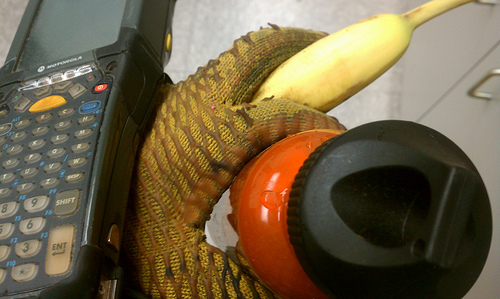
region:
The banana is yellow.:
[255, 22, 460, 114]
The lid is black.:
[290, 120, 498, 295]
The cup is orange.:
[204, 130, 364, 296]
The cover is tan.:
[120, 32, 317, 296]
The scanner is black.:
[3, 5, 143, 297]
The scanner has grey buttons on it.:
[0, 27, 129, 292]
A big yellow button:
[18, 80, 80, 123]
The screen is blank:
[8, 2, 493, 297]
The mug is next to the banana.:
[208, 112, 498, 294]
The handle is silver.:
[458, 57, 497, 101]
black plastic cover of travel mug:
[286, 108, 498, 297]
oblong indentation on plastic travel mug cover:
[314, 151, 439, 259]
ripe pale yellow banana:
[264, 0, 477, 112]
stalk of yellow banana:
[390, 2, 472, 29]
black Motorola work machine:
[6, 1, 161, 296]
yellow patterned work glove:
[164, 23, 226, 292]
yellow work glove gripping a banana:
[176, 6, 453, 131]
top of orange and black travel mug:
[233, 118, 495, 297]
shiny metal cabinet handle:
[460, 56, 499, 108]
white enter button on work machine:
[41, 223, 79, 278]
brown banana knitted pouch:
[215, 19, 378, 135]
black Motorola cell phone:
[10, 11, 135, 284]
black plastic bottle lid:
[293, 111, 497, 285]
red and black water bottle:
[222, 119, 498, 291]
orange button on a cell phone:
[8, 80, 135, 183]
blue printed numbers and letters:
[9, 134, 84, 269]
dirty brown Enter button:
[37, 216, 87, 280]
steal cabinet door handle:
[465, 59, 498, 113]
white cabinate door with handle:
[399, 4, 499, 149]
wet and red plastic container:
[237, 141, 356, 283]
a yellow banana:
[239, 0, 464, 114]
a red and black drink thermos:
[198, 125, 488, 298]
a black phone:
[0, 0, 197, 297]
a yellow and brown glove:
[128, 19, 365, 296]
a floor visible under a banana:
[161, 3, 413, 136]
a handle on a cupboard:
[465, 60, 495, 100]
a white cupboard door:
[412, 51, 497, 279]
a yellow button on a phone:
[26, 92, 65, 113]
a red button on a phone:
[90, 80, 107, 92]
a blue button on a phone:
[80, 98, 101, 112]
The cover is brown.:
[125, 30, 302, 297]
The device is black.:
[4, 1, 162, 296]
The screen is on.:
[3, 8, 176, 119]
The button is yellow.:
[27, 89, 82, 119]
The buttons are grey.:
[9, 55, 136, 285]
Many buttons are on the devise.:
[14, 65, 128, 290]